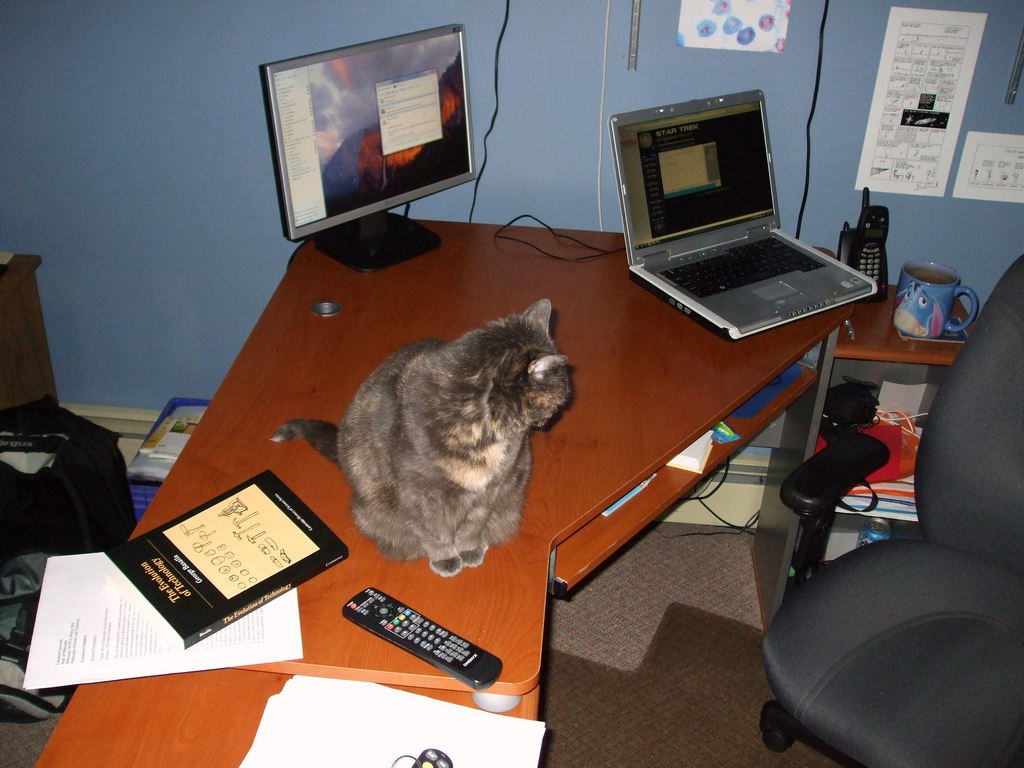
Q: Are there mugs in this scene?
A: Yes, there is a mug.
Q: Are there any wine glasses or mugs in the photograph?
A: Yes, there is a mug.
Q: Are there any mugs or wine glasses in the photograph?
A: Yes, there is a mug.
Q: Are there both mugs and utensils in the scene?
A: No, there is a mug but no utensils.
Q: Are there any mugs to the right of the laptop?
A: Yes, there is a mug to the right of the laptop.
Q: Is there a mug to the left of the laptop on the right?
A: No, the mug is to the right of the laptop.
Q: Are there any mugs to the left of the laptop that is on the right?
A: No, the mug is to the right of the laptop.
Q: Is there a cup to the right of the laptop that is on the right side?
A: No, there is a mug to the right of the laptop.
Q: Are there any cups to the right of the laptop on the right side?
A: No, there is a mug to the right of the laptop.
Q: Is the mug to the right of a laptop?
A: Yes, the mug is to the right of a laptop.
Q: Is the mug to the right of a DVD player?
A: No, the mug is to the right of a laptop.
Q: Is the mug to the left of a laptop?
A: No, the mug is to the right of a laptop.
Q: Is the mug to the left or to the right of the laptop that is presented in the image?
A: The mug is to the right of the laptop.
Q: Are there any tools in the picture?
A: No, there are no tools.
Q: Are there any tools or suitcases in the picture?
A: No, there are no tools or suitcases.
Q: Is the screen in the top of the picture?
A: Yes, the screen is in the top of the image.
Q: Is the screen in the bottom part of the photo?
A: No, the screen is in the top of the image.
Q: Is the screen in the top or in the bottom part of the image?
A: The screen is in the top of the image.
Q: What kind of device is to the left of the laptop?
A: The device is a screen.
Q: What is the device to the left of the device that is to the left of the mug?
A: The device is a screen.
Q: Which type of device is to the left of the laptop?
A: The device is a screen.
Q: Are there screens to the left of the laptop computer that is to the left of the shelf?
A: Yes, there is a screen to the left of the laptop.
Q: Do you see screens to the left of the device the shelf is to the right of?
A: Yes, there is a screen to the left of the laptop.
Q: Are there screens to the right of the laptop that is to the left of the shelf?
A: No, the screen is to the left of the laptop computer.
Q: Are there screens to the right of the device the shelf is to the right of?
A: No, the screen is to the left of the laptop computer.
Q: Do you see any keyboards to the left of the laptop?
A: No, there is a screen to the left of the laptop.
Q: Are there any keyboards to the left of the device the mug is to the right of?
A: No, there is a screen to the left of the laptop.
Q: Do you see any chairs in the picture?
A: Yes, there is a chair.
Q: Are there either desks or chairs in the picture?
A: Yes, there is a chair.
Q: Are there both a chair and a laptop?
A: Yes, there are both a chair and a laptop.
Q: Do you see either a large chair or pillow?
A: Yes, there is a large chair.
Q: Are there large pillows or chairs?
A: Yes, there is a large chair.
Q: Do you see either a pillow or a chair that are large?
A: Yes, the chair is large.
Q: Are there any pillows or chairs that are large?
A: Yes, the chair is large.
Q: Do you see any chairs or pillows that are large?
A: Yes, the chair is large.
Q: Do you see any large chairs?
A: Yes, there is a large chair.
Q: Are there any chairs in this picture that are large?
A: Yes, there is a chair that is large.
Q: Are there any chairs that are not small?
A: Yes, there is a large chair.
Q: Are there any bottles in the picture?
A: No, there are no bottles.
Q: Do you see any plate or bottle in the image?
A: No, there are no bottles or plates.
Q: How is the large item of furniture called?
A: The piece of furniture is a chair.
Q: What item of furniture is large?
A: The piece of furniture is a chair.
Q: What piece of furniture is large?
A: The piece of furniture is a chair.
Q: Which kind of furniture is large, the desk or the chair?
A: The chair is large.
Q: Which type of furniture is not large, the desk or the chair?
A: The desk is not large.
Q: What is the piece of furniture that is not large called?
A: The piece of furniture is a desk.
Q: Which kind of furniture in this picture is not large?
A: The furniture is a desk.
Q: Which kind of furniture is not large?
A: The furniture is a desk.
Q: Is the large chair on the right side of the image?
A: Yes, the chair is on the right of the image.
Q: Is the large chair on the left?
A: No, the chair is on the right of the image.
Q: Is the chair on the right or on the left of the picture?
A: The chair is on the right of the image.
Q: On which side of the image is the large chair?
A: The chair is on the right of the image.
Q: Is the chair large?
A: Yes, the chair is large.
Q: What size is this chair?
A: The chair is large.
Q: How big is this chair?
A: The chair is large.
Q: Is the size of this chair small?
A: No, the chair is large.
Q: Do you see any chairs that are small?
A: No, there is a chair but it is large.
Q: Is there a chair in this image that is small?
A: No, there is a chair but it is large.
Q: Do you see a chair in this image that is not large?
A: No, there is a chair but it is large.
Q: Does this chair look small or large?
A: The chair is large.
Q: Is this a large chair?
A: Yes, this is a large chair.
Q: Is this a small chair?
A: No, this is a large chair.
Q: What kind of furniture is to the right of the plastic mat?
A: The piece of furniture is a chair.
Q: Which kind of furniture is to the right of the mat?
A: The piece of furniture is a chair.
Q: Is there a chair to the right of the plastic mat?
A: Yes, there is a chair to the right of the mat.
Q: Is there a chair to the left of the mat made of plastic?
A: No, the chair is to the right of the mat.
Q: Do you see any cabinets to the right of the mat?
A: No, there is a chair to the right of the mat.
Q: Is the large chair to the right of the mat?
A: Yes, the chair is to the right of the mat.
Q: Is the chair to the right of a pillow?
A: No, the chair is to the right of the mat.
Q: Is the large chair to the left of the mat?
A: No, the chair is to the right of the mat.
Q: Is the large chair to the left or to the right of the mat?
A: The chair is to the right of the mat.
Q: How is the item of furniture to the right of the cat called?
A: The piece of furniture is a chair.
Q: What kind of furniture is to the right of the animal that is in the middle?
A: The piece of furniture is a chair.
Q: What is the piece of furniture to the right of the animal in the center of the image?
A: The piece of furniture is a chair.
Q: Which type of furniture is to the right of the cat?
A: The piece of furniture is a chair.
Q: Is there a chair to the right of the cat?
A: Yes, there is a chair to the right of the cat.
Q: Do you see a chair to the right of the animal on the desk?
A: Yes, there is a chair to the right of the cat.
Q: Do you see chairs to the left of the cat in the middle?
A: No, the chair is to the right of the cat.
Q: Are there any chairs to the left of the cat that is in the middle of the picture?
A: No, the chair is to the right of the cat.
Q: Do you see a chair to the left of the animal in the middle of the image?
A: No, the chair is to the right of the cat.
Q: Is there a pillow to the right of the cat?
A: No, there is a chair to the right of the cat.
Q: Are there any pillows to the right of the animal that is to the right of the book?
A: No, there is a chair to the right of the cat.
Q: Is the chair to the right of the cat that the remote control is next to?
A: Yes, the chair is to the right of the cat.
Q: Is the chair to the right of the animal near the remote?
A: Yes, the chair is to the right of the cat.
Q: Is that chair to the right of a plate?
A: No, the chair is to the right of the cat.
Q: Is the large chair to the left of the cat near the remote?
A: No, the chair is to the right of the cat.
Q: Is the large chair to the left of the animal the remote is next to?
A: No, the chair is to the right of the cat.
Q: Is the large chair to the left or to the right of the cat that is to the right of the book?
A: The chair is to the right of the cat.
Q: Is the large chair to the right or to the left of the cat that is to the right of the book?
A: The chair is to the right of the cat.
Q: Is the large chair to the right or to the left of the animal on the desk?
A: The chair is to the right of the cat.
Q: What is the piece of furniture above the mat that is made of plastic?
A: The piece of furniture is a chair.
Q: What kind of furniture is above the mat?
A: The piece of furniture is a chair.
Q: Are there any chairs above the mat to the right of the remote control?
A: Yes, there is a chair above the mat.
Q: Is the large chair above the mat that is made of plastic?
A: Yes, the chair is above the mat.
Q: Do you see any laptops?
A: Yes, there is a laptop.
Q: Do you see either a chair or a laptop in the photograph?
A: Yes, there is a laptop.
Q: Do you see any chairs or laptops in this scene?
A: Yes, there is a laptop.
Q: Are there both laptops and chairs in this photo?
A: Yes, there are both a laptop and a chair.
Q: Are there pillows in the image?
A: No, there are no pillows.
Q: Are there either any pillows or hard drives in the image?
A: No, there are no pillows or hard drives.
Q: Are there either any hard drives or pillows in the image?
A: No, there are no pillows or hard drives.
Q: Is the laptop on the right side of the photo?
A: Yes, the laptop is on the right of the image.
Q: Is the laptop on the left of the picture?
A: No, the laptop is on the right of the image.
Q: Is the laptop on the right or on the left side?
A: The laptop is on the right of the image.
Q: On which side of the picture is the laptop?
A: The laptop is on the right of the image.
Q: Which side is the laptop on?
A: The laptop is on the right of the image.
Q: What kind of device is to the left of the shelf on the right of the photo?
A: The device is a laptop.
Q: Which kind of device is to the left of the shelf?
A: The device is a laptop.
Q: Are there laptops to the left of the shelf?
A: Yes, there is a laptop to the left of the shelf.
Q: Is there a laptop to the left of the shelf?
A: Yes, there is a laptop to the left of the shelf.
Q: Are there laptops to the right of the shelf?
A: No, the laptop is to the left of the shelf.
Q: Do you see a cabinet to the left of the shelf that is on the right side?
A: No, there is a laptop to the left of the shelf.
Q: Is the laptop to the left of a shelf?
A: Yes, the laptop is to the left of a shelf.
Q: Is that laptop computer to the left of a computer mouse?
A: No, the laptop computer is to the left of a shelf.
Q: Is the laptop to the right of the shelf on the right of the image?
A: No, the laptop is to the left of the shelf.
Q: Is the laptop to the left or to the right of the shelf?
A: The laptop is to the left of the shelf.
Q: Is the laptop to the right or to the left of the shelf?
A: The laptop is to the left of the shelf.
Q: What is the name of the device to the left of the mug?
A: The device is a laptop.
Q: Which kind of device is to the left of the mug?
A: The device is a laptop.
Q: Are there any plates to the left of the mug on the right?
A: No, there is a laptop to the left of the mug.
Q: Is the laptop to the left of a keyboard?
A: No, the laptop is to the left of the mug.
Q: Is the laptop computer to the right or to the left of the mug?
A: The laptop computer is to the left of the mug.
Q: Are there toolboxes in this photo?
A: No, there are no toolboxes.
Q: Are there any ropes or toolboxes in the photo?
A: No, there are no toolboxes or ropes.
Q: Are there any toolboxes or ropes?
A: No, there are no toolboxes or ropes.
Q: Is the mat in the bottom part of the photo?
A: Yes, the mat is in the bottom of the image.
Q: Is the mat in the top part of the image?
A: No, the mat is in the bottom of the image.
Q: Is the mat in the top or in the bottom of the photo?
A: The mat is in the bottom of the image.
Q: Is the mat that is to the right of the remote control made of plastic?
A: Yes, the mat is made of plastic.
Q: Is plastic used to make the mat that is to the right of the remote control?
A: Yes, the mat is made of plastic.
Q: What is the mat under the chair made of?
A: The mat is made of plastic.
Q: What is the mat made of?
A: The mat is made of plastic.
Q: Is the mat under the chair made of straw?
A: No, the mat is made of plastic.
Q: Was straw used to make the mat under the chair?
A: No, the mat is made of plastic.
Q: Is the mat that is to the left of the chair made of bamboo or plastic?
A: The mat is made of plastic.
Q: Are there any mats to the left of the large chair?
A: Yes, there is a mat to the left of the chair.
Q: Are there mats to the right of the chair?
A: No, the mat is to the left of the chair.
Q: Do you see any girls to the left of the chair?
A: No, there is a mat to the left of the chair.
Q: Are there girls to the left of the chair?
A: No, there is a mat to the left of the chair.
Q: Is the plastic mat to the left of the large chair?
A: Yes, the mat is to the left of the chair.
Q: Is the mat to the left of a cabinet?
A: No, the mat is to the left of the chair.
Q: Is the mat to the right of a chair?
A: No, the mat is to the left of a chair.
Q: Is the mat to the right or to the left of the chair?
A: The mat is to the left of the chair.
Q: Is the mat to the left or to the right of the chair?
A: The mat is to the left of the chair.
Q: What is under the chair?
A: The mat is under the chair.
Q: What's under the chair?
A: The mat is under the chair.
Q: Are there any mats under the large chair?
A: Yes, there is a mat under the chair.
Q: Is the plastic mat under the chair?
A: Yes, the mat is under the chair.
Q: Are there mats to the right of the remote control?
A: Yes, there is a mat to the right of the remote control.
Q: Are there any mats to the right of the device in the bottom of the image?
A: Yes, there is a mat to the right of the remote control.